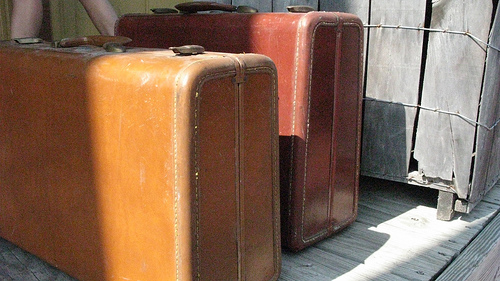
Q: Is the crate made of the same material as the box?
A: Yes, both the crate and the box are made of wood.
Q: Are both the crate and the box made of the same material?
A: Yes, both the crate and the box are made of wood.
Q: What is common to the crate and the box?
A: The material, both the crate and the box are wooden.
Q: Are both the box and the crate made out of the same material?
A: Yes, both the box and the crate are made of wood.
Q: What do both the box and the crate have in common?
A: The material, both the box and the crate are wooden.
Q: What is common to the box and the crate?
A: The material, both the box and the crate are wooden.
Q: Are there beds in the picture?
A: No, there are no beds.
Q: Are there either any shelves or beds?
A: No, there are no beds or shelves.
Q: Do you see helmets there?
A: No, there are no helmets.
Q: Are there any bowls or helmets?
A: No, there are no helmets or bowls.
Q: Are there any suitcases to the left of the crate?
A: Yes, there is a suitcase to the left of the crate.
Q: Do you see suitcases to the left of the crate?
A: Yes, there is a suitcase to the left of the crate.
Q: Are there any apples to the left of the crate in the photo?
A: No, there is a suitcase to the left of the crate.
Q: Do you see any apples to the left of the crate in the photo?
A: No, there is a suitcase to the left of the crate.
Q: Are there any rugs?
A: No, there are no rugs.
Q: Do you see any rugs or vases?
A: No, there are no rugs or vases.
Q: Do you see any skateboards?
A: No, there are no skateboards.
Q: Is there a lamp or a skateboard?
A: No, there are no skateboards or lamps.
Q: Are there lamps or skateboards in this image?
A: No, there are no skateboards or lamps.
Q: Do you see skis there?
A: No, there are no skis.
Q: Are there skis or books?
A: No, there are no skis or books.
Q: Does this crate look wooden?
A: Yes, the crate is wooden.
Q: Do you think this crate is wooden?
A: Yes, the crate is wooden.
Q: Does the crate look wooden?
A: Yes, the crate is wooden.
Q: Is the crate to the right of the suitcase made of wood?
A: Yes, the crate is made of wood.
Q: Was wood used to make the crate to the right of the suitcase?
A: Yes, the crate is made of wood.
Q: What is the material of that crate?
A: The crate is made of wood.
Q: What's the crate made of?
A: The crate is made of wood.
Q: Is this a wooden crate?
A: Yes, this is a wooden crate.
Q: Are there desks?
A: No, there are no desks.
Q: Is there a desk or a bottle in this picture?
A: No, there are no desks or bottles.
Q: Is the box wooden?
A: Yes, the box is wooden.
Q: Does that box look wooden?
A: Yes, the box is wooden.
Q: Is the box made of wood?
A: Yes, the box is made of wood.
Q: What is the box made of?
A: The box is made of wood.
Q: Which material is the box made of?
A: The box is made of wood.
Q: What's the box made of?
A: The box is made of wood.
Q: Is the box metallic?
A: No, the box is wooden.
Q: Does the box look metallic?
A: No, the box is wooden.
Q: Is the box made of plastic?
A: No, the box is made of wood.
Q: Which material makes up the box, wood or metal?
A: The box is made of wood.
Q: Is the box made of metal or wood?
A: The box is made of wood.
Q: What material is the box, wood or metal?
A: The box is made of wood.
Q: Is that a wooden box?
A: Yes, that is a wooden box.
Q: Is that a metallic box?
A: No, that is a wooden box.